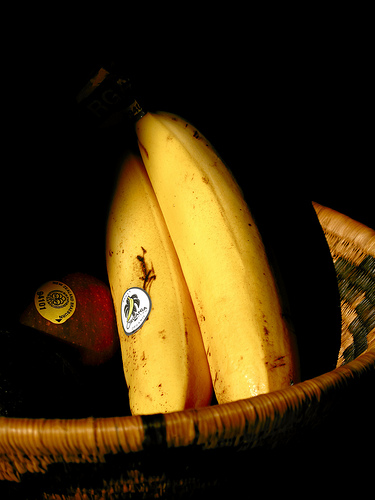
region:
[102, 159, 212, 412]
Yellow banana in basket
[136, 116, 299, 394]
Yellow banana in basket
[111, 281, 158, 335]
Sticker on a banana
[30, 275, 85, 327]
Yellow sticker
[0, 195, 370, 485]
Brown wicker basket holding fruit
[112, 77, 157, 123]
Stem of a banana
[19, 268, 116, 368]
Apple nearly hidden in darkness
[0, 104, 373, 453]
Basket of different fruits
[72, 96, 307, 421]
Two bananas bundled together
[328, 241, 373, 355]
Black markings on basket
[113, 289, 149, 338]
A WHITE STICKER WITH A BANANA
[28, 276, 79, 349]
A YELLOW PRODUCE STICKER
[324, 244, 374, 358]
A WICKER BASKET HANDLE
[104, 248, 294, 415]
A PAIR OF BANANAS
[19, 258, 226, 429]
FRUIT IN A BASKET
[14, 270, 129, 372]
A RED APPLE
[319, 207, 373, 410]
GREEN AND TAN WICKER BASKET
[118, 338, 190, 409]
BROWN SPOTS ON BANANA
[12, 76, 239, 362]
A GROUP OF FRUIT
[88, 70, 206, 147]
A BANANA STEM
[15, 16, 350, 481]
light shines on part of a fruit basket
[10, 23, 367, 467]
a basket of fruit is mostly concealed in shadow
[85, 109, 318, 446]
a pair of bananas in a straw basket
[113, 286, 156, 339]
a sticker on a banana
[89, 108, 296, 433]
yellow bananas have some black spots on them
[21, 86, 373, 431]
different kinds of fruits in a straw basket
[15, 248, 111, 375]
the skin of a red apple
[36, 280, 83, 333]
a sticker affixed to an apple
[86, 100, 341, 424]
banana casts shadow on the side of a straw basket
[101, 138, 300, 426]
two ripe bananas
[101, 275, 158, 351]
sticker on the banana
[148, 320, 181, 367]
yellow part of banana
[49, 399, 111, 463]
basket with bananas in it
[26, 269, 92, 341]
yellow sticker with black writing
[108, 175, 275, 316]
two bananas in basket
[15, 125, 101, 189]
black background of photo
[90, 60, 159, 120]
top part of the banana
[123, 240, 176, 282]
brown spots on bananas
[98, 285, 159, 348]
sticker with a picture on it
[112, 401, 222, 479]
brown basket with black shadow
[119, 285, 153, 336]
green and whie fruit sticker on a banana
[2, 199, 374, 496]
brown wicker basket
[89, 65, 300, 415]
two yellow bananas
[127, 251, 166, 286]
brown mark on banana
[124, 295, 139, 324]
image of a banana on a sticker on a banana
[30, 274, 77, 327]
yellow sticker on an apple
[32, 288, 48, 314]
number on a sticker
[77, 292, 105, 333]
yellow marks on apple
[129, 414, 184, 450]
black stripe on lip of wicker basket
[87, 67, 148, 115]
brown tip of banana